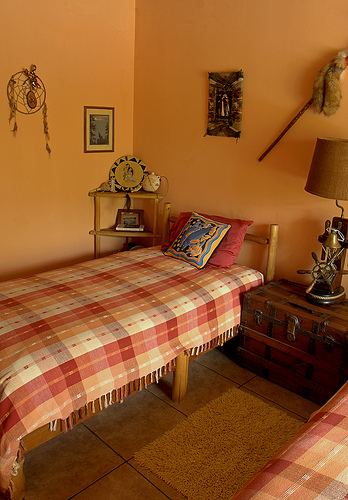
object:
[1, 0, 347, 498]
bedroom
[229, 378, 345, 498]
blanket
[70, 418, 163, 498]
lines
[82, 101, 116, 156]
brown oven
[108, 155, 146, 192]
plate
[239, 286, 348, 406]
cabinet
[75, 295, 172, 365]
comforter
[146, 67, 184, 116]
wall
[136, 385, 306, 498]
mat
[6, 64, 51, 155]
dream catcher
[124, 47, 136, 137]
wall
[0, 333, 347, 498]
floor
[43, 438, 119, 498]
tiles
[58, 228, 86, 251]
wall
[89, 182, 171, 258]
cabinet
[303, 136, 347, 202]
lampshade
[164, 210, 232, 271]
pillow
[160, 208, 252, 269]
pillow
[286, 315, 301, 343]
lock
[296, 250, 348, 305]
ships wheel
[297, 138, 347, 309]
lamp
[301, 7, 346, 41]
wall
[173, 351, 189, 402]
leg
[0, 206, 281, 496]
bed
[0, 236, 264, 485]
bed cover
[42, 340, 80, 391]
fringe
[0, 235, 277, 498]
blanket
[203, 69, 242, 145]
picture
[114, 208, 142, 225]
photo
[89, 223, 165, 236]
shelf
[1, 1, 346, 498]
room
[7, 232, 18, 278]
wall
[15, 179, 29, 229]
wall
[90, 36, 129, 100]
wall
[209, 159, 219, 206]
wall